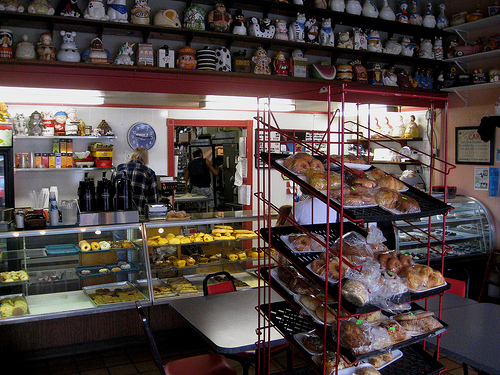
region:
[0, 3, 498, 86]
shelves of collectible cookie jars on shelves above the counter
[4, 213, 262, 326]
a glass bakery counter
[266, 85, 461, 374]
a red cart full of baked goods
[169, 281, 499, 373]
silver tables in front of counter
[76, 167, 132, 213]
three black coffee dispensers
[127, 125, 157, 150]
a blue clock on the wall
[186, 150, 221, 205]
a man in a black shirt back in the kitchen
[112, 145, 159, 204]
a person in a plaid shirt behind the counter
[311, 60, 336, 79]
a watermelon shaped cookie jar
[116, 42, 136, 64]
a white unicorn shaped cookie jar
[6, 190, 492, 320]
bakery's glass display case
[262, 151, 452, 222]
black tray full of baked goods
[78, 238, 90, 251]
Light brown bagels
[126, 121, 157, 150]
blue and silver wall clock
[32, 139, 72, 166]
Multi colored boxes of tea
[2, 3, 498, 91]
many different cookie jars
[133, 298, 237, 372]
red and black metal chair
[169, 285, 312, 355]
gray table in a bakery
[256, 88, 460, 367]
large red metal tray holder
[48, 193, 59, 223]
multicolored white paper drinking cups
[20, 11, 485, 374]
The inside of a bakery shop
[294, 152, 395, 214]
Trays of donuts on top shelf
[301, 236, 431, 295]
Donuts and bread on next shelf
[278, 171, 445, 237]
Metal trays holding pastries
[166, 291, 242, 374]
A silver top table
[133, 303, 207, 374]
Black chair with orange seat and back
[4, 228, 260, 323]
A glass pastry display case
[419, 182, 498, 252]
An oval glass display case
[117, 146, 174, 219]
A person in a blue and beige shirt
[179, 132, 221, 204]
A person in the background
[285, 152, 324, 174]
bagels on the shelf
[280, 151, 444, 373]
different types of pastries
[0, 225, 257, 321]
pastries are on display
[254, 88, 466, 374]
the rack is red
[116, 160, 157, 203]
a checker pattern shirt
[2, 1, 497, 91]
various items on shelf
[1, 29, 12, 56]
a quaker oats package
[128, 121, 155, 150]
clock on the wall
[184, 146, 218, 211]
person in back room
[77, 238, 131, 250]
a row of donuts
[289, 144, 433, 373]
pastries on the shelf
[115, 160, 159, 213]
the shirt is plaid